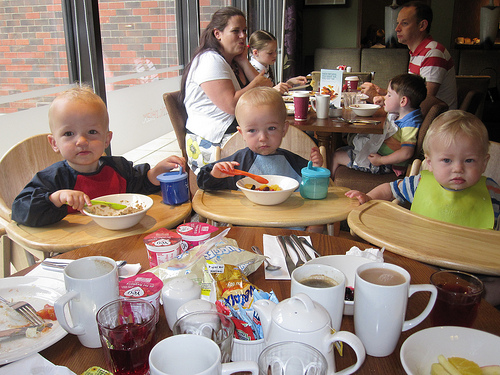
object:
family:
[391, 2, 460, 111]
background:
[2, 0, 493, 131]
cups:
[51, 255, 120, 352]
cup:
[52, 255, 119, 351]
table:
[2, 223, 494, 373]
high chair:
[0, 129, 193, 256]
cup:
[287, 257, 348, 339]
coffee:
[297, 274, 337, 288]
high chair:
[348, 134, 497, 274]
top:
[11, 153, 152, 232]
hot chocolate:
[362, 263, 402, 285]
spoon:
[250, 245, 283, 273]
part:
[195, 185, 350, 227]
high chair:
[194, 123, 364, 227]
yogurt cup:
[140, 228, 185, 268]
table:
[267, 55, 411, 146]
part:
[333, 115, 347, 131]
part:
[192, 96, 215, 123]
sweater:
[177, 45, 248, 147]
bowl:
[348, 103, 382, 117]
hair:
[246, 26, 278, 49]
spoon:
[221, 159, 279, 190]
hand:
[210, 160, 241, 179]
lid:
[302, 157, 332, 181]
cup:
[352, 262, 437, 358]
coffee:
[364, 264, 399, 285]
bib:
[409, 165, 495, 231]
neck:
[416, 174, 487, 203]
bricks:
[123, 19, 155, 57]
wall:
[5, 5, 235, 141]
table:
[336, 196, 498, 285]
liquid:
[106, 332, 143, 367]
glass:
[92, 294, 161, 371]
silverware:
[268, 224, 328, 277]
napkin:
[248, 243, 281, 273]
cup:
[300, 163, 331, 201]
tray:
[194, 174, 358, 234]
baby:
[193, 88, 324, 207]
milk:
[303, 181, 327, 200]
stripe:
[397, 173, 412, 199]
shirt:
[389, 165, 498, 234]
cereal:
[138, 225, 196, 269]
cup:
[142, 227, 181, 269]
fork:
[3, 287, 45, 340]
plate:
[0, 281, 83, 367]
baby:
[10, 81, 189, 231]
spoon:
[81, 199, 128, 211]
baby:
[344, 108, 499, 232]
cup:
[156, 165, 190, 205]